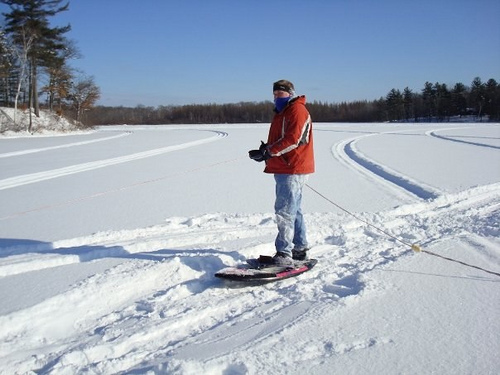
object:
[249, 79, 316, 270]
man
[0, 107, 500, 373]
snow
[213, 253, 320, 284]
board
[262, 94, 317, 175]
coat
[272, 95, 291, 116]
mask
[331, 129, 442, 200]
tracks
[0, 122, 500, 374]
field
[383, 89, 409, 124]
tree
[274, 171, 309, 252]
pants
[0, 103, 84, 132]
hill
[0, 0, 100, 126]
tree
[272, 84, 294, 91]
sweatband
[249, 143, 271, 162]
gloves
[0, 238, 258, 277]
shadow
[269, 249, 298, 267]
shoe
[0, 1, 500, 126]
background